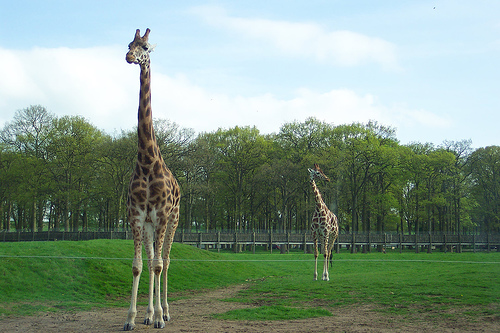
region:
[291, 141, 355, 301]
giraffe has a long neck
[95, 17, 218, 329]
giraffe standing on soil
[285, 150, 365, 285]
giraffe with head twisted to one side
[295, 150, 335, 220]
giraffe with slanted neck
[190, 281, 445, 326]
bare patches in grassy field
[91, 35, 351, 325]
one giraffe eyeing another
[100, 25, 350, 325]
one giraffe following the other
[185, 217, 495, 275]
elevated walkway at edge of enclosure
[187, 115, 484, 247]
trees growing on other side of enclosure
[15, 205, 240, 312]
low mound behind giraffe's legs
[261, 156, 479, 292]
flat ground to giraffe's side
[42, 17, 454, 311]
Two giraffes outside in view.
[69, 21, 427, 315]
some giraffes outside in view.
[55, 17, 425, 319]
Two giraffes walking outside in the open view.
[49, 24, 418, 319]
Large giraffes walking outside in the open view.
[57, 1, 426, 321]
Tall giraffes walking outside in open view.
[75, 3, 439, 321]
Very attractive giraffes walking outside in open view.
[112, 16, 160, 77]
head of a giraffe.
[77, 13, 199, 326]
one very tall giraffe.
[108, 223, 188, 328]
legs of tall giraffe.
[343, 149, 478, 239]
nice set of green trees.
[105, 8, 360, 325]
two giraffes in a zoo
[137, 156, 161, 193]
brown spots on giraffe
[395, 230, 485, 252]
wooden fence along giraffe enclosure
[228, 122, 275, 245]
tall green leafy trees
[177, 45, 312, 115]
white clouds in sky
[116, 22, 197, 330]
giraffe looking at camera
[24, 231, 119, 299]
hill filled with bright green grass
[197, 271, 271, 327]
dirt patch in grassy enclosure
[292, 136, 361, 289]
giraffe looking to the right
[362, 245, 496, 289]
well manicured green grass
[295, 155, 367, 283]
a giraffe walks in the grass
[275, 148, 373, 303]
a giraffe looks to its side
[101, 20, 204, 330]
a giraffe walks through a path worn into the grass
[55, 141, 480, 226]
a row of trees in the background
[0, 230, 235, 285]
a small grassy hill in an enclosure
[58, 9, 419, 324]
two giraffes in an enclosure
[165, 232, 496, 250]
an elevated platform in the background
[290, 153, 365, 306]
the giraffe in the rear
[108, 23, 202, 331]
the giraffe in the foreground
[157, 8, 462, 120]
white clouds in the sky